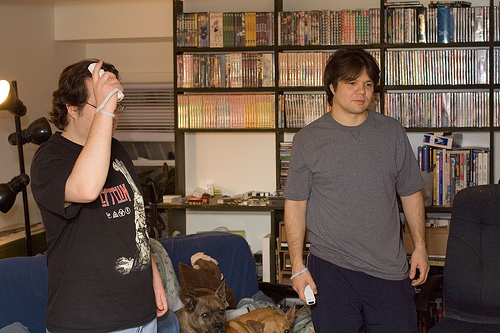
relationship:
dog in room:
[179, 276, 229, 332] [5, 3, 499, 326]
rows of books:
[176, 9, 499, 46] [175, 12, 499, 130]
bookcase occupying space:
[173, 2, 497, 286] [172, 0, 499, 291]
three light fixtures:
[0, 73, 51, 212] [0, 76, 54, 260]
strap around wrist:
[288, 265, 309, 286] [288, 249, 309, 292]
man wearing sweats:
[283, 46, 430, 333] [305, 249, 419, 333]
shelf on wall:
[172, 0, 499, 291] [173, 2, 499, 310]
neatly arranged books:
[176, 11, 275, 129] [175, 12, 499, 130]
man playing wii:
[28, 58, 170, 332] [85, 61, 130, 122]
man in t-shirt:
[29, 59, 170, 332] [28, 133, 155, 332]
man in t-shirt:
[283, 46, 430, 333] [285, 110, 427, 280]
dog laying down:
[223, 299, 302, 333] [175, 281, 299, 333]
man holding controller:
[29, 59, 170, 332] [84, 57, 122, 118]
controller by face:
[84, 57, 122, 118] [74, 74, 118, 137]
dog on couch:
[223, 298, 298, 331] [0, 232, 260, 332]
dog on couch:
[168, 279, 235, 333] [0, 232, 260, 332]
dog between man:
[168, 279, 235, 333] [283, 41, 430, 333]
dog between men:
[168, 279, 235, 333] [28, 58, 184, 330]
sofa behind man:
[0, 227, 273, 330] [28, 58, 170, 332]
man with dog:
[28, 58, 170, 332] [173, 284, 226, 327]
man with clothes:
[28, 58, 170, 332] [230, 290, 314, 330]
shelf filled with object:
[172, 0, 499, 291] [181, 13, 184, 45]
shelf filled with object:
[172, 0, 499, 291] [206, 182, 213, 196]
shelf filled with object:
[172, 0, 499, 291] [422, 133, 452, 149]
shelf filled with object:
[172, 0, 499, 291] [416, 8, 425, 43]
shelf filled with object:
[172, 0, 499, 291] [326, 11, 330, 45]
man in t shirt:
[29, 59, 170, 332] [30, 130, 157, 332]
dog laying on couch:
[168, 279, 235, 333] [409, 164, 488, 331]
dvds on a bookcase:
[173, 52, 182, 90] [173, 2, 500, 274]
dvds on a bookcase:
[193, 12, 199, 47] [173, 2, 500, 274]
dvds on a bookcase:
[241, 92, 245, 128] [173, 2, 500, 274]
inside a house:
[127, 14, 438, 329] [36, 8, 482, 328]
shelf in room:
[177, 125, 276, 137] [5, 3, 499, 326]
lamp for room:
[0, 75, 31, 117] [8, 33, 463, 297]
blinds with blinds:
[115, 80, 180, 132] [115, 80, 180, 132]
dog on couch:
[168, 279, 235, 333] [1, 227, 296, 331]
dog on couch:
[223, 299, 302, 333] [1, 227, 296, 331]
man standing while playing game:
[28, 58, 170, 332] [89, 65, 119, 106]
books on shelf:
[176, 1, 498, 126] [174, 7, 482, 220]